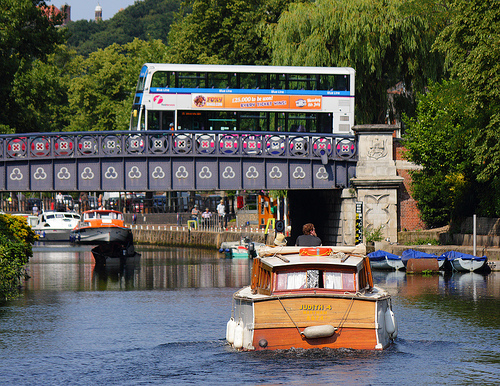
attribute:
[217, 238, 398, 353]
boat — orange, white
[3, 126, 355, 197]
bridge — grey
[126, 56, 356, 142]
bus — white, double decker, blue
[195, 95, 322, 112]
ad — orange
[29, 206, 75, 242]
boat — white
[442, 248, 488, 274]
boat — small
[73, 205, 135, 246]
boat — gold, white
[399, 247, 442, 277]
boat — small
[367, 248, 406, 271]
boat — small, fishing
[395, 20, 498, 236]
tree — large